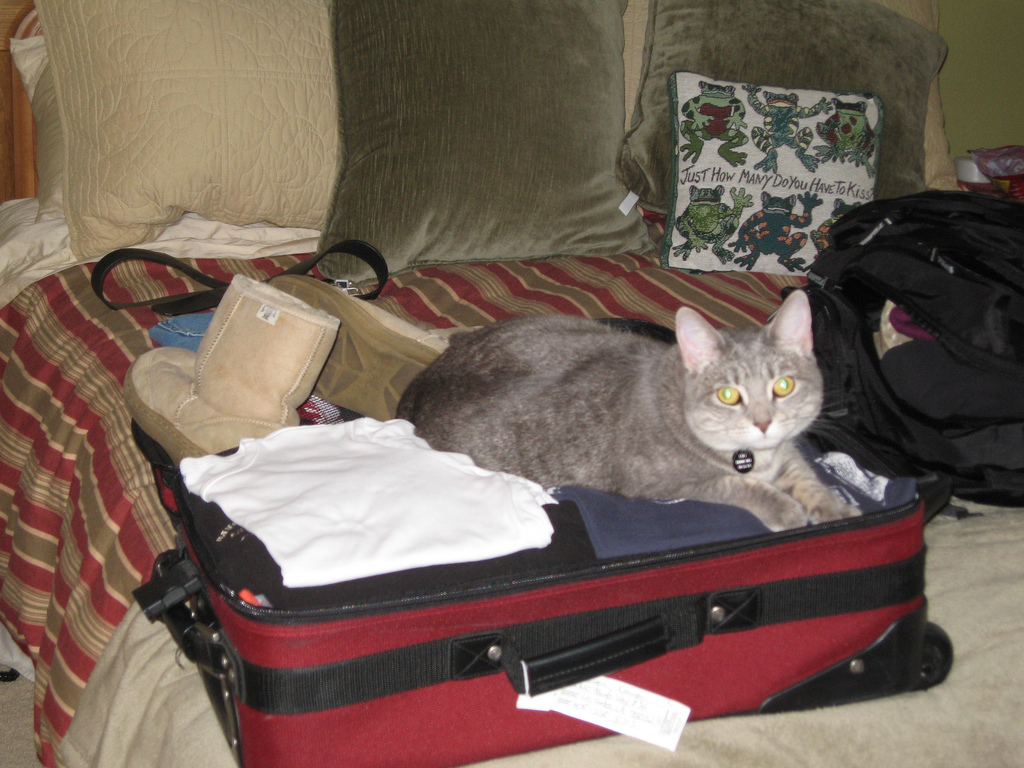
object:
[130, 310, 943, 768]
suitcase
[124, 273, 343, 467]
boots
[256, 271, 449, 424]
boots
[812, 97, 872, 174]
frog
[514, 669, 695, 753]
tag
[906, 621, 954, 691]
wheel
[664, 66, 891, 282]
throw pillow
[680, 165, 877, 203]
lettering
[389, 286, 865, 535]
cat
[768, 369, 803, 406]
eye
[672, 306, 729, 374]
ear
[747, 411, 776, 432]
nose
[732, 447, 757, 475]
tag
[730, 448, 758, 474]
collar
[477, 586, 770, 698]
handle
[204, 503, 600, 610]
shirt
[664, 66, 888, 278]
pillow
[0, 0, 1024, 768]
bed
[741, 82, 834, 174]
frog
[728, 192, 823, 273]
frog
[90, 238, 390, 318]
belt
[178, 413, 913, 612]
clothes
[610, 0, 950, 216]
pillow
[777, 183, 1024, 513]
duffel bag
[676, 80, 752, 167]
frog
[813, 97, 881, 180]
frog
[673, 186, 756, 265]
frog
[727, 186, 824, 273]
frog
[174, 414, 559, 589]
shirt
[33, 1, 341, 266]
pillow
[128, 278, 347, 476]
uggs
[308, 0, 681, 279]
pillow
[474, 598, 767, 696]
luggage tag